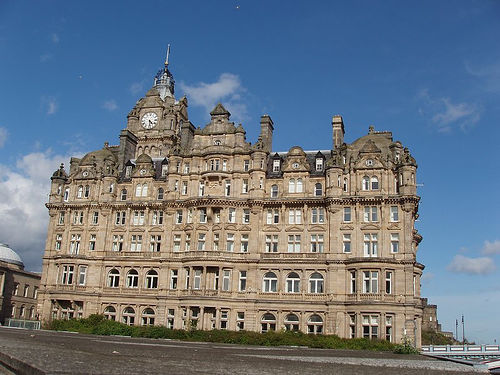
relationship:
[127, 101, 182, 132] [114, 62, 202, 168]
clock on tower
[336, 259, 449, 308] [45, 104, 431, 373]
windows on castle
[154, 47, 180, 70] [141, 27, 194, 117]
flag on pole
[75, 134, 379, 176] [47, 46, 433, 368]
parapets on building